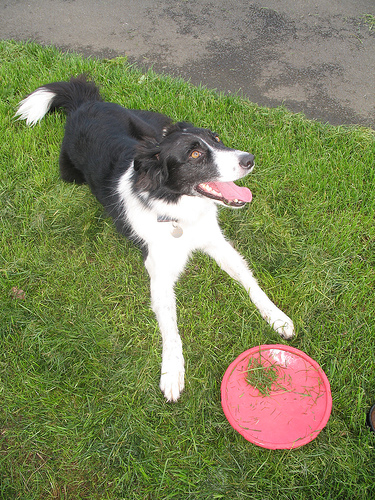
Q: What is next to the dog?
A: A red toy.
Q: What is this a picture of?
A: Head of the dog.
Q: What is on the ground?
A: A red toy.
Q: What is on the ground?
A: A red dog toy.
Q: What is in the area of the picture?
A: Green grass.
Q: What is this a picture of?
A: The head of a dog.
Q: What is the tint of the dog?
A: Black and white.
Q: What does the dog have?
A: Front legs.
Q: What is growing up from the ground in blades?
A: Grass.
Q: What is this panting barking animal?
A: Dog.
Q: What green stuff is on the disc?
A: Grass.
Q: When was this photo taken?
A: During the day.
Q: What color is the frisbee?
A: Pink.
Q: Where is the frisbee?
A: In front of the dog.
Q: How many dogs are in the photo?
A: One.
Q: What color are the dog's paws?
A: White.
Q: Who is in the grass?
A: The dog.